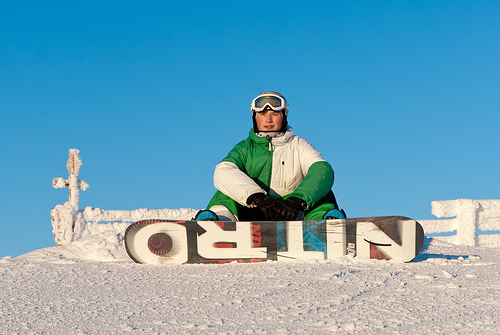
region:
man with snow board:
[110, 79, 418, 269]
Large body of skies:
[16, 10, 223, 140]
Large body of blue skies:
[8, 6, 214, 131]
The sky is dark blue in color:
[13, 11, 219, 121]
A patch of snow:
[70, 271, 258, 331]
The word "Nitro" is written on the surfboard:
[128, 215, 423, 268]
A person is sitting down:
[135, 65, 411, 266]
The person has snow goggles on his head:
[247, 90, 287, 110]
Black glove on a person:
[250, 195, 272, 210]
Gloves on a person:
[258, 193, 303, 216]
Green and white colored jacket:
[220, 130, 335, 202]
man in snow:
[204, 76, 336, 267]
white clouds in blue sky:
[388, 103, 443, 137]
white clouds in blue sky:
[215, 26, 263, 47]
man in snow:
[215, 83, 330, 271]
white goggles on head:
[252, 94, 288, 111]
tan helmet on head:
[256, 92, 291, 112]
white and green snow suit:
[208, 134, 339, 216]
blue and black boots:
[193, 209, 348, 223]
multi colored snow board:
[126, 219, 424, 261]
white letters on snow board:
[133, 222, 419, 259]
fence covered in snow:
[51, 202, 499, 246]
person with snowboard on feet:
[123, 89, 425, 270]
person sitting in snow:
[119, 89, 426, 270]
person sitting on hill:
[123, 91, 425, 263]